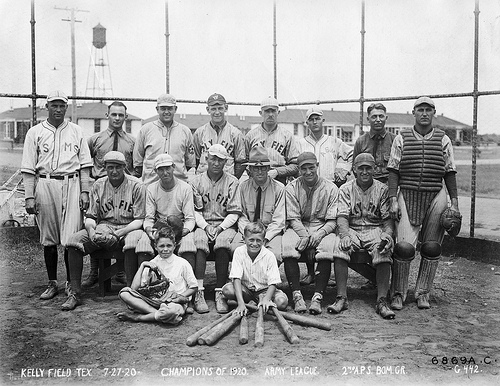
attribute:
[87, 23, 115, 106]
tower — large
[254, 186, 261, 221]
tie — dark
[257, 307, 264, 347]
bat — wood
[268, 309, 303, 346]
bat — wood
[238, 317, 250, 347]
bat — wood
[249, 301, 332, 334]
bat — wood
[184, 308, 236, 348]
bat — wood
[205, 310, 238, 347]
bat — wood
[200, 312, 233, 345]
bat — wood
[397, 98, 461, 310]
player — posing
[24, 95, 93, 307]
player — posing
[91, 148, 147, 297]
player — posing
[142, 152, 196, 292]
player — posing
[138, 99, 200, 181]
player — posing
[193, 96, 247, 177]
player — posing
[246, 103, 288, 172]
player — posing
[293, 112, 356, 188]
player — posing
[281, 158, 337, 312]
player — posing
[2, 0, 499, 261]
fence — tall